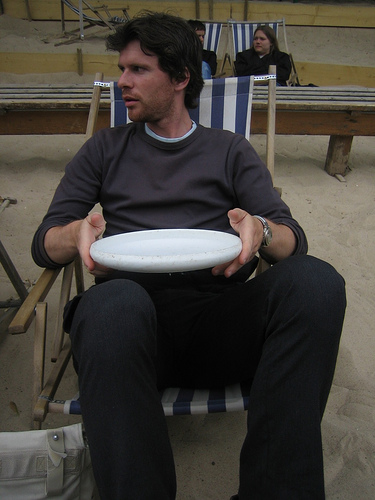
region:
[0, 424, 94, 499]
some beige fabric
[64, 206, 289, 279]
two hands holding a frisbee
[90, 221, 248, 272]
the frisbee is round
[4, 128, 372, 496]
the ground is covered with sand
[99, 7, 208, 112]
the man's hair is shaggy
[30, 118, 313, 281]
the man is wearing a sweater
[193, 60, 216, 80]
the person wearing jeans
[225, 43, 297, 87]
the woman is wearing a jacket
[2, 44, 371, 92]
a yellow strip on the ground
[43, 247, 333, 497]
the man is wearing dark pants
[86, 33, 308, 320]
this is a man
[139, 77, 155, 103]
the man is light skinned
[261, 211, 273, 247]
this is a watch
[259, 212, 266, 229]
the watch is metallic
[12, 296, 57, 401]
this is a chair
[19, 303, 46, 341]
the chair is wooden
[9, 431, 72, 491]
this is a bag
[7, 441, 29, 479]
the bag is white in color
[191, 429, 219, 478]
this is the ground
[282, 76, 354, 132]
this is a bench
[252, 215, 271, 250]
a silver watch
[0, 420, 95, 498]
a beige messenger bag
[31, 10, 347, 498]
a man sitting on a beach chair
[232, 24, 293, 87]
a woman sitting on a beach chair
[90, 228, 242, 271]
a white frisbee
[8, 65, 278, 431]
a blue and white beach chair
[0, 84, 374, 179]
a wooden bench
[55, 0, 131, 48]
a beach chair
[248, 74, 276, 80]
a metal bracket on a beach chair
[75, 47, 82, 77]
a wooden steak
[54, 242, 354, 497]
the man is wearing black pants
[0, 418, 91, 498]
the bag is on the ground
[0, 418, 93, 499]
the bag is on the sand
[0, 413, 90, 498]
the bag is tan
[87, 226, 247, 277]
the man is holding a frisbee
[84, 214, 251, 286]
the frisbee is white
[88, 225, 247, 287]
the frisbee is upside down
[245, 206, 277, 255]
the man is wearing a watch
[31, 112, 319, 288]
the man is wearing a grey shirt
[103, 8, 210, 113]
the man has short hair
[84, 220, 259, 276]
a white plate in a man's hands.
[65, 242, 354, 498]
a pair of black pants.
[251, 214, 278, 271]
a metal wrist watch.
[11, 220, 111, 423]
an arm rest on a chair.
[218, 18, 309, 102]
a person sitting.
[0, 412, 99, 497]
a bag on the sand.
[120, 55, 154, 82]
a left human eye.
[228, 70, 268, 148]
a blue stripe on a chair.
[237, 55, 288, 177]
the back of a chair.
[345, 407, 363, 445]
a section of sand.